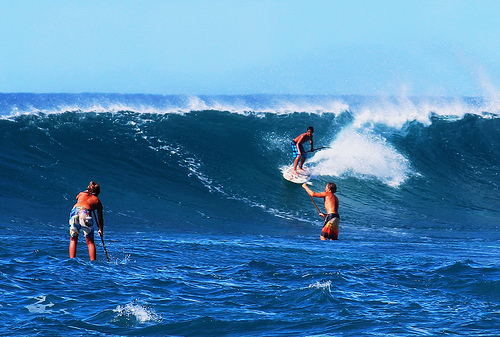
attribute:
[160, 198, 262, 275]
water — blue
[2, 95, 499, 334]
bluewater — blue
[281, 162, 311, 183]
surf board — white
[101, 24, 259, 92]
sky — blue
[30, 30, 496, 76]
clouds — white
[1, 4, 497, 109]
sky — blue, clear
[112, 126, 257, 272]
water — blue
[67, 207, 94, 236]
swimming trunks — blue, white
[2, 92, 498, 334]
water — blue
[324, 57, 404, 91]
sky — blue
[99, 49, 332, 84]
clouds — white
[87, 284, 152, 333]
wave — blue, big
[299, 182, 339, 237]
guy — yellow, orange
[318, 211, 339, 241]
swimming trunks — black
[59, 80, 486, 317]
water — blue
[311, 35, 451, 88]
sky — white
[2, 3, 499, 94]
sky — blue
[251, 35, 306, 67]
clouds — white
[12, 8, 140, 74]
clouds — white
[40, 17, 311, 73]
clouds — white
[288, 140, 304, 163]
swimming trunks — blue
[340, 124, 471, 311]
water — white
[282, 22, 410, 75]
clouds — white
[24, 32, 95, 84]
clouds — white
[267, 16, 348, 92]
clouds — white